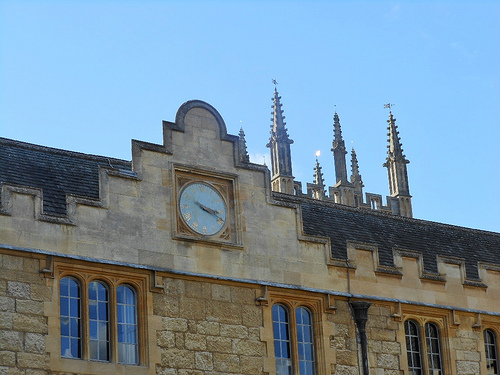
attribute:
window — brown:
[294, 297, 321, 373]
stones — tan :
[152, 276, 272, 373]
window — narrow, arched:
[292, 303, 317, 373]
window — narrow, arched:
[269, 304, 294, 374]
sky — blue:
[2, 3, 131, 157]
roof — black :
[1, 133, 498, 283]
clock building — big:
[141, 94, 257, 265]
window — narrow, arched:
[55, 272, 150, 363]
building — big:
[0, 78, 500, 373]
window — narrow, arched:
[268, 307, 298, 371]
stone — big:
[457, 313, 479, 368]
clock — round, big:
[177, 176, 229, 238]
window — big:
[57, 268, 84, 363]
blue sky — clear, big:
[0, 0, 497, 80]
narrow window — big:
[293, 306, 320, 373]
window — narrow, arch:
[394, 314, 427, 373]